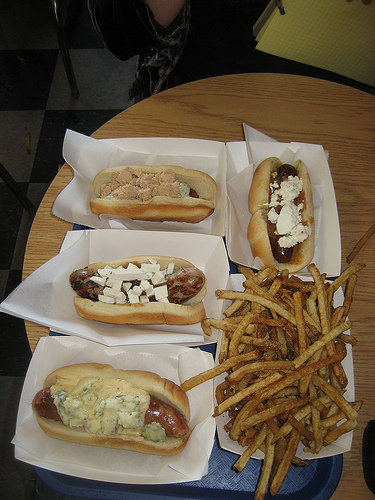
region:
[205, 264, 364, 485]
a bunch of french fries in a paper container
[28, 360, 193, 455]
a brat with toppings on a bun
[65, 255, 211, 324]
a brat with toppings on a bun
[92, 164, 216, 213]
a brat with toppings on a bun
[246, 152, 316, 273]
a brat with toppings on a bun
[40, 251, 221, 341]
a brat and bun on a paper in a paper container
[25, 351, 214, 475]
a brat and bun on a paper in a paper container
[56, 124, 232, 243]
a brat and bun on a paper in a paper container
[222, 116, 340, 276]
a brat and bun on a paper in a paper container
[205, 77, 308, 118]
the grain of the wood of a table top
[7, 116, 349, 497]
hotdogs and french fries on a tray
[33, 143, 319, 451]
four hotdogs on a tray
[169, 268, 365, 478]
container of french fries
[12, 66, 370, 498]
wood laminate table food is on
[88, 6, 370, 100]
person sitting at the table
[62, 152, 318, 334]
two hotdogs with white garnish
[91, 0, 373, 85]
black shirt person is wearing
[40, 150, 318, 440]
four hotdogs in buns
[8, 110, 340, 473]
white napkins and containers hotdogs are on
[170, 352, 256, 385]
french fry touching hotdog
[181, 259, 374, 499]
a pile of fries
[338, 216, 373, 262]
fry laying on the table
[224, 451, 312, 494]
fries hanging over the side of the container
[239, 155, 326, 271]
toppings covering the hot dog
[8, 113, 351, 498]
four hot dogs on a tray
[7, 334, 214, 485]
hot dog on a piece of wax paper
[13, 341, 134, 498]
blue tray hanging over the table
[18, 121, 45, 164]
garbage on the ground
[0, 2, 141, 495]
black and white tile on the floor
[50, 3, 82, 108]
silver chair leg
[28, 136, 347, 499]
blue rectangular plastic tray with rounded corners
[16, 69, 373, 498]
circular light brown wooden table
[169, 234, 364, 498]
batch of brown and yellow french fries in basket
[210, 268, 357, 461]
rectangular paper basket with fries in it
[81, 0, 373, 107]
person wearing black clothes sitting at table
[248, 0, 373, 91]
white lined notebook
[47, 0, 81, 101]
silver metal chair leg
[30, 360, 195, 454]
sausage sandwich next to fries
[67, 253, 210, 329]
sausage sandwich with white cubes on it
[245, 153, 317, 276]
sausage sandwich with white cheese on it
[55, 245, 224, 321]
a large bratwurst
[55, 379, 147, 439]
this is blue cheese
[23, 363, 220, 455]
there is bleu cheese on the sandwich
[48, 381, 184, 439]
chunks of blue cheese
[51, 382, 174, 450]
pieces of bleu cheese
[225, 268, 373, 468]
a small basket of french fries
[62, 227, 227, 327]
this is a sausage sandwich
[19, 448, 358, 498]
this is a blue plastic tray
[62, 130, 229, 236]
the sandwich is wrapped in paper on a tray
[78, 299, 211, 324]
this is a hotdog bun